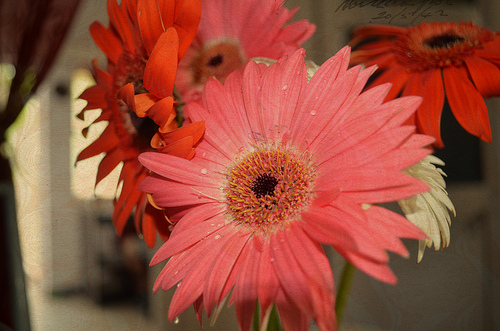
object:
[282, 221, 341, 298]
petal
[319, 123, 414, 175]
petal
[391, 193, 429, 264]
petal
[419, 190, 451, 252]
petal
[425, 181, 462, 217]
petal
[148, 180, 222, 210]
petal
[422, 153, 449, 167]
petal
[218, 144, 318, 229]
center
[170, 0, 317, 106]
flower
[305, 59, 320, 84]
white petals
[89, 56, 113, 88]
petals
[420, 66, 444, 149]
petal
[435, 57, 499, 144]
petal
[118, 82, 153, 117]
petal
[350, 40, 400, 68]
petal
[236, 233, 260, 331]
petal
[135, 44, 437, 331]
flower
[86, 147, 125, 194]
petal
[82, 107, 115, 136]
petal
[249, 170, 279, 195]
circle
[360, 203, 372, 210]
specks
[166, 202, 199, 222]
pink petal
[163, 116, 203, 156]
petals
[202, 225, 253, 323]
petal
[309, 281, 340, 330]
petal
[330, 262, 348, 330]
stem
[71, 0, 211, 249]
flower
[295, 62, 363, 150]
petal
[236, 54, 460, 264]
flower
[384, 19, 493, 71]
center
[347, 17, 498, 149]
flower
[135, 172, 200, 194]
petals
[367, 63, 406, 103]
petal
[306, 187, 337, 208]
petal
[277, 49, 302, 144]
petal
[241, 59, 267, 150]
petal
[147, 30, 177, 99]
petal